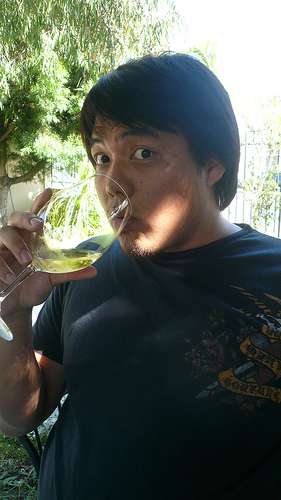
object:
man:
[0, 52, 281, 500]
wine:
[30, 181, 111, 276]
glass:
[0, 173, 132, 342]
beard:
[120, 240, 159, 258]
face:
[90, 116, 205, 257]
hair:
[78, 53, 240, 209]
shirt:
[32, 224, 281, 500]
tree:
[0, 0, 184, 229]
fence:
[227, 132, 281, 237]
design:
[181, 282, 281, 411]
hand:
[0, 187, 97, 311]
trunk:
[0, 143, 8, 224]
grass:
[0, 419, 48, 500]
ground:
[0, 392, 68, 500]